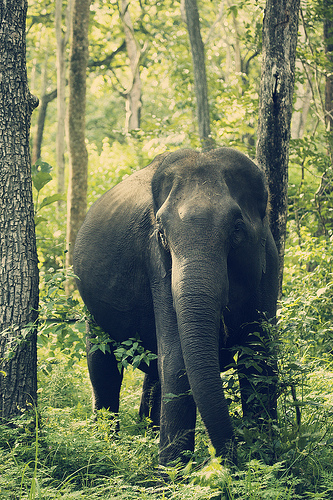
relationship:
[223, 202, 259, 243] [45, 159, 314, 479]
eye of elephant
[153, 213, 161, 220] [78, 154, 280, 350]
eye of elephant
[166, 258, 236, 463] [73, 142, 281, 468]
trunk of elephant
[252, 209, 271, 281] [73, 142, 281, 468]
ears of elephant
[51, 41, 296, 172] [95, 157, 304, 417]
trees behind elephant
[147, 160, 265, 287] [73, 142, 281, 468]
face of elephant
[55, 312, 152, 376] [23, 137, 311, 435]
leaves rubbing elephant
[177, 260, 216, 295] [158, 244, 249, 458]
wrinkles in trunk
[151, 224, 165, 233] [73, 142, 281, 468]
eyelashes of elephant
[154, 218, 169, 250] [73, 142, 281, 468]
eye of elephant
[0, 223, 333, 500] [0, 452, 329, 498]
grass on ground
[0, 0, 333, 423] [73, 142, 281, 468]
trees behind elephant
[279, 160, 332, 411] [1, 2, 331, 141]
bushes behind trees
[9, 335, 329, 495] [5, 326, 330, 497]
grass on ground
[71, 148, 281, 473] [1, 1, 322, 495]
animal standing in woods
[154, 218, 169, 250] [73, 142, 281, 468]
eye belonging to elephant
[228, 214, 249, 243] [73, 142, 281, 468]
eye belonging to elephant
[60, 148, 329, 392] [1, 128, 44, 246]
animal standing next to trunk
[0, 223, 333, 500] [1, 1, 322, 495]
grass growing in woods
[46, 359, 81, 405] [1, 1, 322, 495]
fern growing in woods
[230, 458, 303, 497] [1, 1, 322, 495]
fern growing in woods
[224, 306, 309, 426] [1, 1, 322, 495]
shrub growing in woods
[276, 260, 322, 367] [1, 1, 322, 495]
shrub growing in woods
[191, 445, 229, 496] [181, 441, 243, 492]
sunlight shining on ferns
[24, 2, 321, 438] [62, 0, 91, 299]
sunlight shining on tree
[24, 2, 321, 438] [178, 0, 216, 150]
sunlight shining on tree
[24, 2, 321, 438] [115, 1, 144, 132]
sunlight shining on tree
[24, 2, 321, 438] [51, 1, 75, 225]
sunlight shining on tree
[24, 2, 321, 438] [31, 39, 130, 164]
sunlight shining on tree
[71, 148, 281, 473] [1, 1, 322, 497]
animal standing in jungle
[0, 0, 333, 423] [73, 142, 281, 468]
trees beside elephant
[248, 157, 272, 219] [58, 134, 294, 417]
hair on elephant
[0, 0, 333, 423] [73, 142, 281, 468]
trees standing next to elephant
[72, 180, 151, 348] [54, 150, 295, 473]
belly of elephant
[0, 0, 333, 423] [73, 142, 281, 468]
trees back behind elephant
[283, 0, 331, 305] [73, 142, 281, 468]
woods back behind elephant